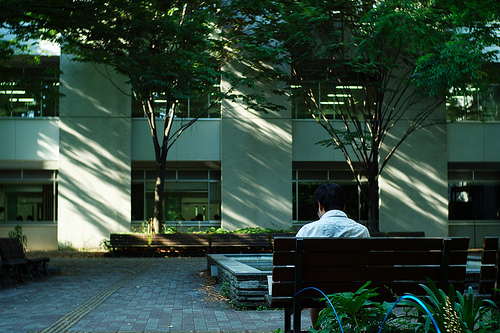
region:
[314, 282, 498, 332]
tropical plantsin the foreground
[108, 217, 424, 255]
plants peek over a string of far benches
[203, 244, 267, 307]
slate topped wall surrounds a tree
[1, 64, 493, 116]
fluorescent lights show on seconf floor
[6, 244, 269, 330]
a varied color bricked courtyard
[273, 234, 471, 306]
slated wood park bench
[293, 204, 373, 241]
man wears a white shirt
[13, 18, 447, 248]
sun shows on the wall of the builing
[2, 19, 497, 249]
an office building with white walls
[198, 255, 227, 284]
a box for electric mounted on stone wall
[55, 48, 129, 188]
shadows from trees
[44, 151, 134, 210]
light from sun up above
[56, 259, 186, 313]
brick layout for pedestrians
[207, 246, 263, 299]
low to the ground perimeter made of brick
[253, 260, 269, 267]
possibly water for a fountain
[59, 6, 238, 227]
trees alongside building creating shade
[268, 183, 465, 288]
person sitting on bench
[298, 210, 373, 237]
white shirt has a collar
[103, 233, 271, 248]
line of benches for people, but they're all empty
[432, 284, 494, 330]
plants for landscaping purposes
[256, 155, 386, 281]
The person is sitting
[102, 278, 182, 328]
The pavement is brick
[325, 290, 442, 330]
The plants are green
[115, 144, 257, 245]
The window is in the building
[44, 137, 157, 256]
The shadows are on the side of the building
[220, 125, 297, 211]
The building is white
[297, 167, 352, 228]
The person's hair is dark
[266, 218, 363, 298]
The bench is wooden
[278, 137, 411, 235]
The window has smaller glass panels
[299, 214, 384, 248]
The man has a white shirt on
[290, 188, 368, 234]
Man sitting on a bench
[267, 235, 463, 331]
Wood bench man is sitting on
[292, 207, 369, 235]
white shirt the man is wearing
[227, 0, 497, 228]
tall tree planted in front of the building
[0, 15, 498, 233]
White building in the distance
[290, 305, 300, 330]
Back left leg of the bench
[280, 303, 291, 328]
left front leg of the bench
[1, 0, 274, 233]
Tall tree planted in front of the white building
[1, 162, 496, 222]
Windows on the first floor of the white building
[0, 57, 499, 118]
Second floor of the white building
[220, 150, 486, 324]
man sitting on a bench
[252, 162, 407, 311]
man sitting on a bench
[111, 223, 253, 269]
the bench is brown